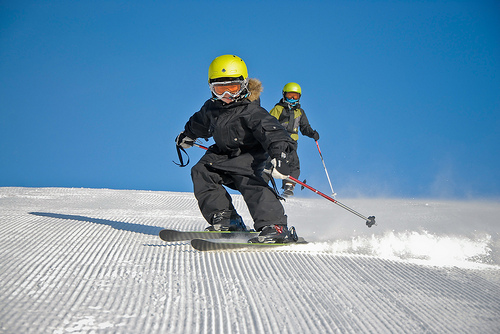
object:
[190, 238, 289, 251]
skiis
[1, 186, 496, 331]
slope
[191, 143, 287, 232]
black pants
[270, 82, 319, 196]
child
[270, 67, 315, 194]
skier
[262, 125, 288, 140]
pocket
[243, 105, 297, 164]
sleeve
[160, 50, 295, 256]
skier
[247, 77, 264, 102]
fur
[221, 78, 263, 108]
hood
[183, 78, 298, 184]
coat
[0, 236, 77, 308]
ridge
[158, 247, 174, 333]
ridge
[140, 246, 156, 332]
ridge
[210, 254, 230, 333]
ridge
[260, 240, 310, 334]
ridge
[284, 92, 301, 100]
goggles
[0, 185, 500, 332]
no object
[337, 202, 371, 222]
silver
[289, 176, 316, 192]
red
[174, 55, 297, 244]
child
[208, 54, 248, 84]
helmet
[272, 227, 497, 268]
sfresh snow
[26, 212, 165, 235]
shadow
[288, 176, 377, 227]
poles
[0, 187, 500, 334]
lines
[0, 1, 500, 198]
sky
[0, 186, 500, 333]
hill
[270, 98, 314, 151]
coat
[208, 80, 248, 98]
goggles